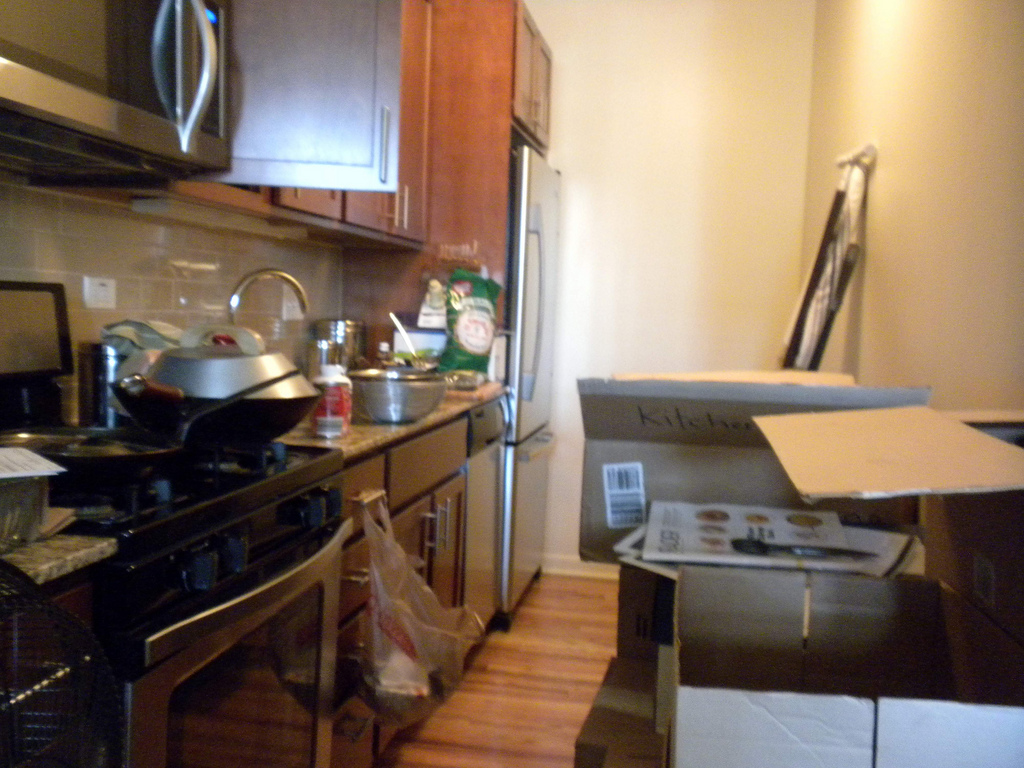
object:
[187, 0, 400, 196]
cabinet door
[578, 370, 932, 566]
box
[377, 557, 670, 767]
floor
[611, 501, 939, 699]
box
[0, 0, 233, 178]
microwave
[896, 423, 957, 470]
cardboard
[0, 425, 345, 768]
oven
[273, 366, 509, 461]
counter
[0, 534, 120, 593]
counter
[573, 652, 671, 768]
counter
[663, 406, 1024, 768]
box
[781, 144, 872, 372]
object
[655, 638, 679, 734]
counter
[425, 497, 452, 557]
handle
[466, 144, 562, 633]
refrigerator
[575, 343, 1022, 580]
counter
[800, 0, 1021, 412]
wall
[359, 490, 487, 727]
bag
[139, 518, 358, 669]
handle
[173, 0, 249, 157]
handle